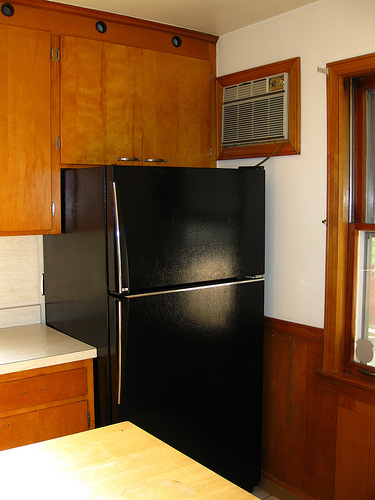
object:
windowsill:
[322, 64, 349, 374]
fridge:
[43, 164, 265, 495]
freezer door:
[106, 166, 266, 297]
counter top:
[0, 321, 97, 375]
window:
[351, 230, 375, 367]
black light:
[171, 33, 182, 48]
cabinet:
[0, 0, 55, 237]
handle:
[111, 181, 129, 297]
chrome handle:
[117, 155, 141, 162]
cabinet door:
[59, 34, 142, 164]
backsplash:
[0, 303, 42, 328]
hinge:
[48, 48, 55, 65]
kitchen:
[0, 0, 374, 499]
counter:
[0, 322, 97, 447]